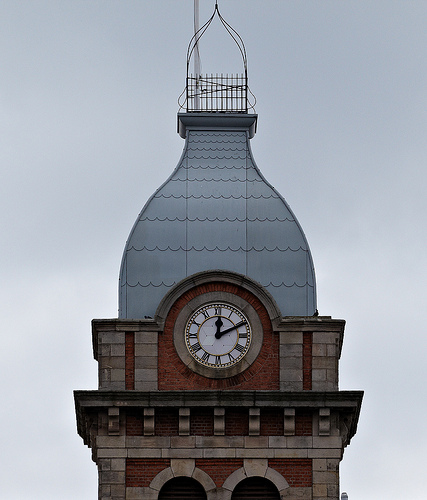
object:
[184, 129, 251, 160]
waved grooves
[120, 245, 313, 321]
waved grooves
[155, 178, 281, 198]
waved grooves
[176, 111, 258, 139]
roof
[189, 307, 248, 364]
numbers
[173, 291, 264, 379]
clock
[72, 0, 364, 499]
building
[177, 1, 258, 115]
top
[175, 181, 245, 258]
wall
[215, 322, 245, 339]
hand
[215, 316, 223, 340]
hand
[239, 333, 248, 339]
3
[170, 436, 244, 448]
rust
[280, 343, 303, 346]
stone line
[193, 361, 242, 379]
rust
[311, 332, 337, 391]
bricks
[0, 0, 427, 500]
sky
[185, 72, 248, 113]
metal gate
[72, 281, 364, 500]
red tower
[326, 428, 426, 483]
water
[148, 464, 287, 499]
arches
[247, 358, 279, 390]
bricks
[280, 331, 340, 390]
pillars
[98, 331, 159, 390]
pillars